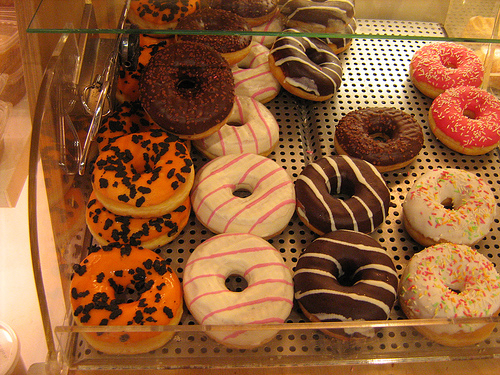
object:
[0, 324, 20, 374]
plate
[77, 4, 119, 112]
table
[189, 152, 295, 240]
doughnuts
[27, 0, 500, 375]
display case